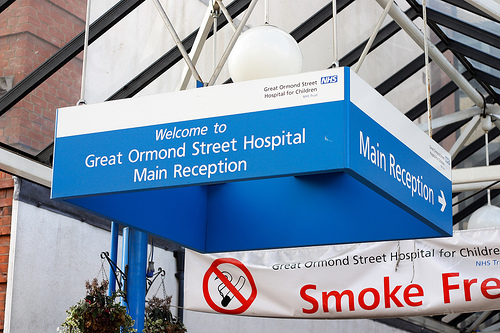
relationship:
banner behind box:
[178, 208, 496, 309] [48, 68, 454, 254]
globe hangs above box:
[226, 23, 300, 85] [48, 68, 454, 254]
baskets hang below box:
[60, 279, 185, 331] [48, 68, 454, 254]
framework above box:
[155, 2, 225, 83] [48, 68, 454, 254]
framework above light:
[155, 2, 225, 83] [226, 24, 307, 84]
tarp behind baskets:
[11, 202, 181, 316] [60, 279, 185, 331]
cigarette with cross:
[210, 268, 245, 311] [206, 257, 258, 311]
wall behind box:
[178, 248, 494, 331] [48, 68, 454, 254]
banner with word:
[180, 225, 499, 319] [296, 270, 424, 314]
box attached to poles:
[28, 57, 454, 251] [54, 3, 458, 129]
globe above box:
[192, 11, 309, 84] [48, 68, 454, 254]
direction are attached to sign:
[353, 130, 451, 211] [47, 80, 455, 257]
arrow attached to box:
[436, 186, 446, 216] [48, 68, 454, 254]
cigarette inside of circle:
[210, 268, 245, 311] [199, 252, 254, 316]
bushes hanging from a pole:
[56, 275, 184, 330] [101, 226, 175, 286]